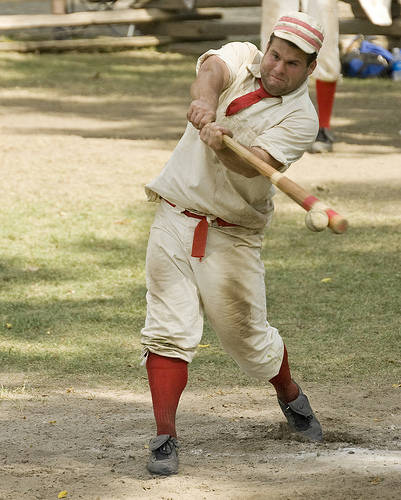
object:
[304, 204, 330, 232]
ball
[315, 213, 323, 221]
white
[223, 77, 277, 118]
tie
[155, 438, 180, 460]
laces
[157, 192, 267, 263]
belt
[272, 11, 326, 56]
hat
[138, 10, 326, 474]
baseball player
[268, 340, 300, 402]
sock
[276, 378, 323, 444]
cleats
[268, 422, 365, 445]
hole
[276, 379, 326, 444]
foot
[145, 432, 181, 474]
cleat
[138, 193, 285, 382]
pants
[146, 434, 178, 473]
shoe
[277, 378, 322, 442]
shoe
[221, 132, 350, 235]
ball bat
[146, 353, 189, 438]
sock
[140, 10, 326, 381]
baseball uniform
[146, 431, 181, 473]
shoes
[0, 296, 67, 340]
shadow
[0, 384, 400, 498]
dirt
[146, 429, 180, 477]
foot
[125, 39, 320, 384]
uniform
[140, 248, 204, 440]
leg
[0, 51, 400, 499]
ground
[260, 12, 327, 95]
head